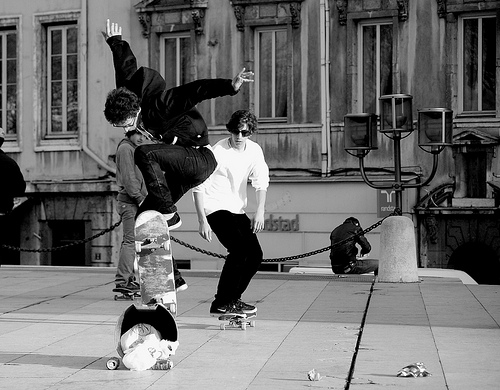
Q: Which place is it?
A: It is a sidewalk.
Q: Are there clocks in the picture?
A: No, there are no clocks.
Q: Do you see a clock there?
A: No, there are no clocks.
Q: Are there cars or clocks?
A: No, there are no clocks or cars.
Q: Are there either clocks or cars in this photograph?
A: No, there are no clocks or cars.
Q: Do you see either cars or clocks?
A: No, there are no clocks or cars.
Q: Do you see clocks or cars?
A: No, there are no clocks or cars.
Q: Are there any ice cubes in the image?
A: No, there are no ice cubes.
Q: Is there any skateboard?
A: Yes, there is a skateboard.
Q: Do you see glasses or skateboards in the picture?
A: Yes, there is a skateboard.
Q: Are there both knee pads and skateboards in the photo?
A: No, there is a skateboard but no knee pads.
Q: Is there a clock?
A: No, there are no clocks.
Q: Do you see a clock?
A: No, there are no clocks.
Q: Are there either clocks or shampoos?
A: No, there are no clocks or shampoos.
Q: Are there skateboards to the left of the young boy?
A: Yes, there is a skateboard to the left of the boy.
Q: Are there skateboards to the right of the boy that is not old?
A: No, the skateboard is to the left of the boy.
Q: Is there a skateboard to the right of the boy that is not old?
A: No, the skateboard is to the left of the boy.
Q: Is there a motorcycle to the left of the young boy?
A: No, there is a skateboard to the left of the boy.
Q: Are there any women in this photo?
A: No, there are no women.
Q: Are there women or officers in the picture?
A: No, there are no women or officers.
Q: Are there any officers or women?
A: No, there are no women or officers.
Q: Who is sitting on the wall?
A: The man is sitting on the wall.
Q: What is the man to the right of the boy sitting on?
A: The man is sitting on the wall.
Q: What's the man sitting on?
A: The man is sitting on the wall.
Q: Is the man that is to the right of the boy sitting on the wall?
A: Yes, the man is sitting on the wall.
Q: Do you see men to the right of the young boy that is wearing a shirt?
A: Yes, there is a man to the right of the boy.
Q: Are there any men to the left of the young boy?
A: No, the man is to the right of the boy.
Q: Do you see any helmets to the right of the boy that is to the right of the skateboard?
A: No, there is a man to the right of the boy.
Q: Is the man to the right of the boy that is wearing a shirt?
A: Yes, the man is to the right of the boy.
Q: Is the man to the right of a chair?
A: No, the man is to the right of the boy.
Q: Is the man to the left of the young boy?
A: No, the man is to the right of the boy.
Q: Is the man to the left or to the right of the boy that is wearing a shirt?
A: The man is to the right of the boy.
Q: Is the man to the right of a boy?
A: Yes, the man is to the right of a boy.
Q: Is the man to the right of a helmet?
A: No, the man is to the right of a boy.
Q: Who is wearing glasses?
A: The boy is wearing glasses.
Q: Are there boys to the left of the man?
A: Yes, there is a boy to the left of the man.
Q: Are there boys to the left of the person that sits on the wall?
A: Yes, there is a boy to the left of the man.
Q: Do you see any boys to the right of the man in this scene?
A: No, the boy is to the left of the man.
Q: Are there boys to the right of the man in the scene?
A: No, the boy is to the left of the man.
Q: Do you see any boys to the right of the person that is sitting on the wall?
A: No, the boy is to the left of the man.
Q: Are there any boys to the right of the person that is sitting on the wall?
A: No, the boy is to the left of the man.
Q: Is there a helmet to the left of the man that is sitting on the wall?
A: No, there is a boy to the left of the man.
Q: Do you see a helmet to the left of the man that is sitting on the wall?
A: No, there is a boy to the left of the man.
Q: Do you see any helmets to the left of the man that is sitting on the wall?
A: No, there is a boy to the left of the man.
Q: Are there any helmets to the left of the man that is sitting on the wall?
A: No, there is a boy to the left of the man.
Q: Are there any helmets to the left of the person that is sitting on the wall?
A: No, there is a boy to the left of the man.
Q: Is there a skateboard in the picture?
A: Yes, there is a skateboard.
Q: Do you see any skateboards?
A: Yes, there is a skateboard.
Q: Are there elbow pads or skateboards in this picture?
A: Yes, there is a skateboard.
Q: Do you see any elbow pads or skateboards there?
A: Yes, there is a skateboard.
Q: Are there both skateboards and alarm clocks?
A: No, there is a skateboard but no alarm clocks.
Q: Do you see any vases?
A: No, there are no vases.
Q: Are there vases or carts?
A: No, there are no vases or carts.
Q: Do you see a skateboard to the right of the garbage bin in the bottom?
A: Yes, there is a skateboard to the right of the trash can.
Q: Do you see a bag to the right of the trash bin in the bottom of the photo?
A: No, there is a skateboard to the right of the garbage can.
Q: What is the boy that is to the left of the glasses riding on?
A: The boy is riding on a skateboard.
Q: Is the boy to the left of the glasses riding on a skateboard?
A: Yes, the boy is riding on a skateboard.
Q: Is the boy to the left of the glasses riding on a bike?
A: No, the boy is riding on a skateboard.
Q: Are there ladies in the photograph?
A: No, there are no ladies.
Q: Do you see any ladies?
A: No, there are no ladies.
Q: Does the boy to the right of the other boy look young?
A: Yes, the boy is young.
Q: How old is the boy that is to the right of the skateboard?
A: The boy is young.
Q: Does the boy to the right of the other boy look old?
A: No, the boy is young.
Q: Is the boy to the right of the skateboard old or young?
A: The boy is young.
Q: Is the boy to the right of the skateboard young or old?
A: The boy is young.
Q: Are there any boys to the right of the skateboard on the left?
A: Yes, there is a boy to the right of the skateboard.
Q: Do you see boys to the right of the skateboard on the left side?
A: Yes, there is a boy to the right of the skateboard.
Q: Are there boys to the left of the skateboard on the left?
A: No, the boy is to the right of the skateboard.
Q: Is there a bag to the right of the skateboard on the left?
A: No, there is a boy to the right of the skateboard.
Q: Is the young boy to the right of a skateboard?
A: Yes, the boy is to the right of a skateboard.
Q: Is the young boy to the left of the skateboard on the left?
A: No, the boy is to the right of the skateboard.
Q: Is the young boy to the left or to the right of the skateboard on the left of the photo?
A: The boy is to the right of the skateboard.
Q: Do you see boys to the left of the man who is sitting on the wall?
A: Yes, there is a boy to the left of the man.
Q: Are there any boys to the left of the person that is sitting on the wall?
A: Yes, there is a boy to the left of the man.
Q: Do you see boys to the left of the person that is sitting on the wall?
A: Yes, there is a boy to the left of the man.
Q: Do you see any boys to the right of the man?
A: No, the boy is to the left of the man.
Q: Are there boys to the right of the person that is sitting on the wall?
A: No, the boy is to the left of the man.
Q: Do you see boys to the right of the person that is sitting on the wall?
A: No, the boy is to the left of the man.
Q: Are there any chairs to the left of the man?
A: No, there is a boy to the left of the man.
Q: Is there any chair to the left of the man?
A: No, there is a boy to the left of the man.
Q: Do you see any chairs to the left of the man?
A: No, there is a boy to the left of the man.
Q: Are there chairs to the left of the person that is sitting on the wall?
A: No, there is a boy to the left of the man.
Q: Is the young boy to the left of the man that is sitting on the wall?
A: Yes, the boy is to the left of the man.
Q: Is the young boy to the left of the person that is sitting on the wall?
A: Yes, the boy is to the left of the man.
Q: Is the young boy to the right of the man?
A: No, the boy is to the left of the man.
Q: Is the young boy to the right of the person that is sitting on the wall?
A: No, the boy is to the left of the man.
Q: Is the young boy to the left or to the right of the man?
A: The boy is to the left of the man.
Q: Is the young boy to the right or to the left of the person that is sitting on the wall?
A: The boy is to the left of the man.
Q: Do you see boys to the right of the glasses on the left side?
A: Yes, there is a boy to the right of the glasses.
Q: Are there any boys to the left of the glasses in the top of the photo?
A: No, the boy is to the right of the glasses.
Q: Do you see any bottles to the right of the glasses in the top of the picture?
A: No, there is a boy to the right of the glasses.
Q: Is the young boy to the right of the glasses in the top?
A: Yes, the boy is to the right of the glasses.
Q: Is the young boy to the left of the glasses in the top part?
A: No, the boy is to the right of the glasses.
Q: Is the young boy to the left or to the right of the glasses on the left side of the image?
A: The boy is to the right of the glasses.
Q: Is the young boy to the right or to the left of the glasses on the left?
A: The boy is to the right of the glasses.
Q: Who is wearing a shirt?
A: The boy is wearing a shirt.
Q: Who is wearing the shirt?
A: The boy is wearing a shirt.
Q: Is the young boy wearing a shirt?
A: Yes, the boy is wearing a shirt.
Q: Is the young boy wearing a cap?
A: No, the boy is wearing a shirt.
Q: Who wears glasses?
A: The boy wears glasses.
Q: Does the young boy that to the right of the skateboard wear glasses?
A: Yes, the boy wears glasses.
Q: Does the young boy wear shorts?
A: No, the boy wears glasses.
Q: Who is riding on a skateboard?
A: The boy is riding on a skateboard.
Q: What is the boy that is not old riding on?
A: The boy is riding on a skateboard.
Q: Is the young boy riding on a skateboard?
A: Yes, the boy is riding on a skateboard.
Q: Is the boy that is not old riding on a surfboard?
A: No, the boy is riding on a skateboard.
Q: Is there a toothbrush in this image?
A: No, there are no toothbrushes.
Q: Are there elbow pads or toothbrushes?
A: No, there are no toothbrushes or elbow pads.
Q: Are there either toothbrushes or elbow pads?
A: No, there are no toothbrushes or elbow pads.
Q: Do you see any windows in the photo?
A: Yes, there is a window.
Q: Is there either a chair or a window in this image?
A: Yes, there is a window.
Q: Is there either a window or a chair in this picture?
A: Yes, there is a window.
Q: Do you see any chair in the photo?
A: No, there are no chairs.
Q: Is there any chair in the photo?
A: No, there are no chairs.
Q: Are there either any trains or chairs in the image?
A: No, there are no chairs or trains.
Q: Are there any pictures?
A: No, there are no pictures.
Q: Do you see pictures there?
A: No, there are no pictures.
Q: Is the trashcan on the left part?
A: Yes, the trashcan is on the left of the image.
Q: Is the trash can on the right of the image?
A: No, the trash can is on the left of the image.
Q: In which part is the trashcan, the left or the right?
A: The trashcan is on the left of the image.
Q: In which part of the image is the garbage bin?
A: The garbage bin is on the left of the image.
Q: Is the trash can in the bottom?
A: Yes, the trash can is in the bottom of the image.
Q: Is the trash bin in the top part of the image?
A: No, the trash bin is in the bottom of the image.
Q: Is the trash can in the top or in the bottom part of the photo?
A: The trash can is in the bottom of the image.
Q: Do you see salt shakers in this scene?
A: No, there are no salt shakers.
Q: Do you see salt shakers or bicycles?
A: No, there are no salt shakers or bicycles.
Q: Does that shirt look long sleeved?
A: Yes, the shirt is long sleeved.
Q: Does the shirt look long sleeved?
A: Yes, the shirt is long sleeved.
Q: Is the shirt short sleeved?
A: No, the shirt is long sleeved.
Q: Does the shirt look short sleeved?
A: No, the shirt is long sleeved.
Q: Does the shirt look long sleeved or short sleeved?
A: The shirt is long sleeved.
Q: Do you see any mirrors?
A: No, there are no mirrors.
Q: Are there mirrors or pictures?
A: No, there are no mirrors or pictures.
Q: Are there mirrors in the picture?
A: No, there are no mirrors.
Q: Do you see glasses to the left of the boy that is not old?
A: Yes, there are glasses to the left of the boy.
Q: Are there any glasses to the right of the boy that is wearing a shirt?
A: No, the glasses are to the left of the boy.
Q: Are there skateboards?
A: Yes, there is a skateboard.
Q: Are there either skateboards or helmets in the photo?
A: Yes, there is a skateboard.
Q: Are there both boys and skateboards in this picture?
A: Yes, there are both a skateboard and a boy.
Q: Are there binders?
A: No, there are no binders.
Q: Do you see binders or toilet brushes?
A: No, there are no binders or toilet brushes.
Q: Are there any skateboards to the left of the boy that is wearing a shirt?
A: Yes, there is a skateboard to the left of the boy.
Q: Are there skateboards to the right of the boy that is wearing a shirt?
A: No, the skateboard is to the left of the boy.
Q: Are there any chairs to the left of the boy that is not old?
A: No, there is a skateboard to the left of the boy.